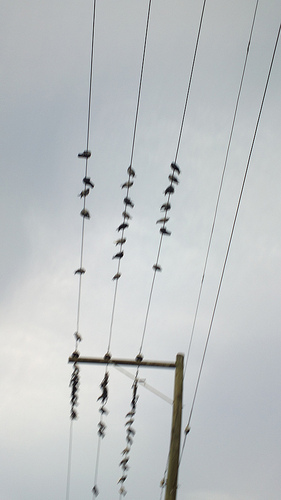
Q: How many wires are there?
A: Five.